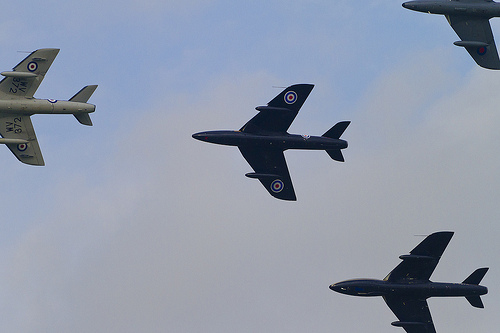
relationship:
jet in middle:
[182, 77, 360, 207] [149, 80, 371, 234]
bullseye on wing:
[280, 87, 302, 108] [236, 81, 319, 131]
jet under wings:
[6, 76, 30, 145] [1, 44, 61, 169]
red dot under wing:
[25, 60, 39, 70] [4, 37, 64, 102]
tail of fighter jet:
[318, 116, 357, 168] [182, 77, 360, 207]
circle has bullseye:
[280, 87, 302, 108] [282, 89, 299, 106]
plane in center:
[182, 77, 360, 207] [149, 80, 371, 234]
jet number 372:
[0, 49, 99, 164] [9, 114, 26, 141]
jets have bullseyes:
[1, 0, 498, 330] [269, 89, 300, 195]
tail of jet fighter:
[318, 116, 357, 168] [182, 77, 360, 207]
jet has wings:
[182, 77, 360, 207] [236, 78, 317, 205]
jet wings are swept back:
[182, 77, 360, 207] [236, 78, 317, 205]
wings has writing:
[1, 44, 61, 169] [6, 76, 30, 145]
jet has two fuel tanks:
[182, 77, 360, 207] [240, 100, 289, 183]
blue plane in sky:
[182, 77, 360, 207] [1, 0, 498, 330]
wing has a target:
[236, 81, 319, 131] [280, 87, 302, 108]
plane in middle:
[182, 77, 360, 207] [149, 80, 371, 234]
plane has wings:
[182, 77, 360, 207] [236, 78, 317, 205]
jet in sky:
[325, 229, 490, 332] [1, 0, 498, 330]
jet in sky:
[188, 82, 351, 202] [1, 0, 498, 330]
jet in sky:
[400, 0, 499, 72] [1, 0, 498, 330]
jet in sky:
[0, 49, 99, 164] [1, 0, 498, 330]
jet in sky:
[330, 231, 490, 330] [1, 0, 498, 330]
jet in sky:
[400, 0, 498, 68] [1, 0, 498, 330]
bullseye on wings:
[282, 89, 299, 106] [269, 89, 300, 195]